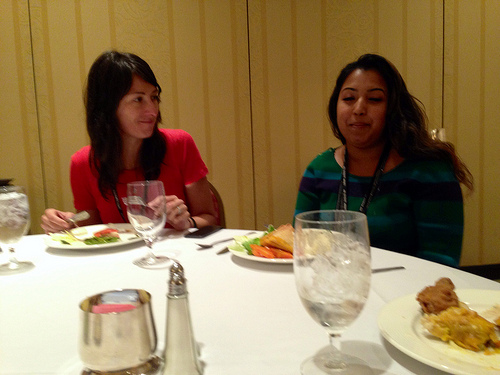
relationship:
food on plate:
[229, 220, 297, 267] [227, 245, 291, 279]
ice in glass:
[308, 261, 363, 294] [282, 201, 379, 329]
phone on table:
[183, 218, 225, 250] [191, 260, 276, 356]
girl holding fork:
[57, 41, 213, 245] [115, 188, 177, 241]